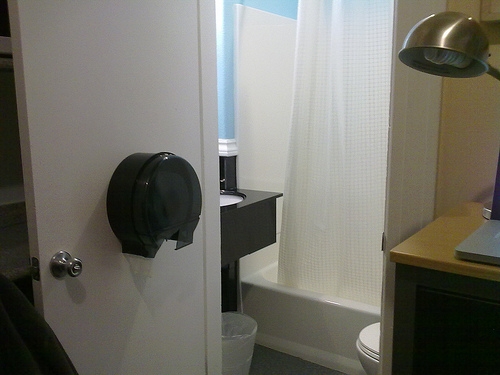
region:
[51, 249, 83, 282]
The metallic door lock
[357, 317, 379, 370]
The partially blocked toilet bowl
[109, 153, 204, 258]
The dark bathroom paper roll holder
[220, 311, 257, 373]
A waste basket on the floor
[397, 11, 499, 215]
The metallic indoor lighting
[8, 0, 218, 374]
A white bathroom door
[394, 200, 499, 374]
An indoor counter top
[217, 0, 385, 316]
The white bathroom curtains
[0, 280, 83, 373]
A piece of dark clothing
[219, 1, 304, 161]
The blue wall background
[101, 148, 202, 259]
paper dispenser on bathroom door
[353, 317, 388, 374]
white toilet bowl in bathroom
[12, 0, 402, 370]
door of bathroom is open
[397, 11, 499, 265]
silver lamp on tan shelf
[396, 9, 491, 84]
lamp with energy efficient bulb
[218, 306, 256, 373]
white trash can on floor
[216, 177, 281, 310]
black and white sink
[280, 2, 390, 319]
white shower curtain inside bathtub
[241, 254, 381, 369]
low white bath tub in bathroom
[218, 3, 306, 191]
white and blue bathroom walls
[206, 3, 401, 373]
A bathroom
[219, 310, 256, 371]
A clear trash bin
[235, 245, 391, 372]
A white bathtub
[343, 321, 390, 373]
A white toilet with a white toilet seat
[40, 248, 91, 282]
A silver door knob on a door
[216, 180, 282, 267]
A black bathroom sink countertop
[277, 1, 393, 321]
A long white shower curtain hanging up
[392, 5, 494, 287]
A silver desk lamp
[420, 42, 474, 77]
An energy efficient white light bulb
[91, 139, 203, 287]
A black toilet paper holder on the door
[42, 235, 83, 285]
THE DOOR KNOB IS SILVER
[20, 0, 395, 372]
THE DOOR IS OPEN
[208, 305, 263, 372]
THE TRASH CAN IS WHITE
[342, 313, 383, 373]
THE TOILET IS WHITE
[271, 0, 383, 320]
THE SHOWER CURTAIN IS WHITE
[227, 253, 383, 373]
THE BATH TUB IS WHITE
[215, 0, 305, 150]
THE WALL IS PAINTED BLUE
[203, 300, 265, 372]
THE TRASH CAN HAS A CLEAR BAG IN IT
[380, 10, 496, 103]
THIS IS A LAMP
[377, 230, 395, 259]
THIS IS THE EDGE OF A STRIKEPLATE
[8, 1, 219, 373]
Bathroom with white door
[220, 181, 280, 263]
Black bathroom counter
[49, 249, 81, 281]
Silver doorknob on white door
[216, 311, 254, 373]
white plastic garbage can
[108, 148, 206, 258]
Gray toilet dispenser hanging on door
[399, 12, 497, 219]
Silver lamp on wooden table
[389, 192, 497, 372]
Wooden table beneath lamp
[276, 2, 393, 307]
Bathtub with white shower curtain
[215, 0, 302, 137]
Light blue bathroom wall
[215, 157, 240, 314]
Black bathroom wall